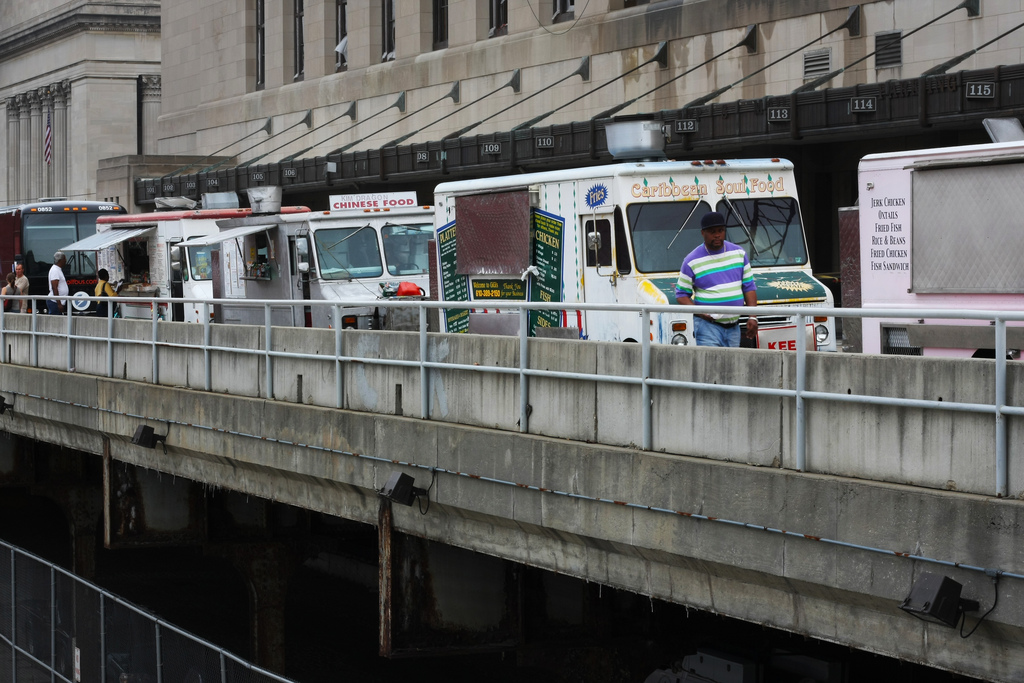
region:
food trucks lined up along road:
[2, 146, 1023, 352]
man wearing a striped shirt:
[676, 212, 754, 345]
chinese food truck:
[321, 189, 433, 222]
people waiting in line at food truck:
[43, 246, 146, 314]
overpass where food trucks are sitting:
[2, 285, 1015, 674]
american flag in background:
[35, 101, 61, 194]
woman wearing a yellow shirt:
[91, 266, 120, 305]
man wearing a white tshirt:
[46, 249, 75, 316]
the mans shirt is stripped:
[705, 271, 738, 304]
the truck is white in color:
[591, 285, 626, 324]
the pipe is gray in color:
[783, 350, 818, 442]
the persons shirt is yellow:
[91, 276, 117, 303]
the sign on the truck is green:
[441, 246, 457, 297]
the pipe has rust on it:
[672, 497, 835, 564]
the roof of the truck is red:
[157, 209, 193, 223]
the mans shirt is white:
[46, 263, 70, 306]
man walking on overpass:
[669, 210, 774, 353]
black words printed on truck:
[866, 178, 914, 302]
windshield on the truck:
[621, 197, 726, 274]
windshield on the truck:
[716, 197, 816, 271]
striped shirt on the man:
[680, 240, 764, 313]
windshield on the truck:
[302, 226, 388, 283]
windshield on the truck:
[384, 217, 436, 274]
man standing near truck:
[37, 248, 76, 302]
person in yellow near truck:
[87, 261, 120, 306]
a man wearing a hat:
[678, 153, 795, 261]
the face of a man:
[682, 183, 747, 257]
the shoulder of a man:
[660, 239, 706, 297]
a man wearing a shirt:
[669, 151, 818, 332]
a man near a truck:
[597, 178, 822, 357]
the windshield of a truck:
[572, 142, 847, 273]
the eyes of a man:
[686, 208, 751, 262]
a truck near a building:
[489, 74, 838, 309]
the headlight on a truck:
[768, 267, 868, 353]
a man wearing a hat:
[681, 195, 748, 256]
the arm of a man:
[645, 267, 722, 326]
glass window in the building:
[368, 0, 397, 65]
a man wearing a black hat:
[697, 212, 723, 232]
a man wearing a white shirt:
[48, 269, 68, 298]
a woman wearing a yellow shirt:
[92, 276, 115, 306]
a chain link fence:
[16, 548, 152, 679]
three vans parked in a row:
[90, 200, 759, 349]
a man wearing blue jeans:
[684, 301, 745, 353]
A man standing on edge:
[674, 205, 772, 361]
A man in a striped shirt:
[678, 221, 771, 332]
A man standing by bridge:
[675, 219, 780, 375]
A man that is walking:
[671, 227, 757, 330]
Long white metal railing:
[18, 300, 1009, 523]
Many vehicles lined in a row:
[36, 204, 922, 363]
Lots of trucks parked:
[21, 213, 954, 376]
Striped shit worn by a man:
[674, 217, 748, 328]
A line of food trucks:
[32, 134, 1000, 438]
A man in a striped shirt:
[656, 195, 770, 396]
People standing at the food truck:
[24, 245, 143, 331]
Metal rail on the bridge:
[525, 284, 947, 523]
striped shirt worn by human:
[684, 240, 757, 313]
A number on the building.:
[963, 81, 993, 97]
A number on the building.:
[768, 100, 794, 120]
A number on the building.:
[673, 118, 706, 131]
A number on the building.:
[656, 122, 676, 132]